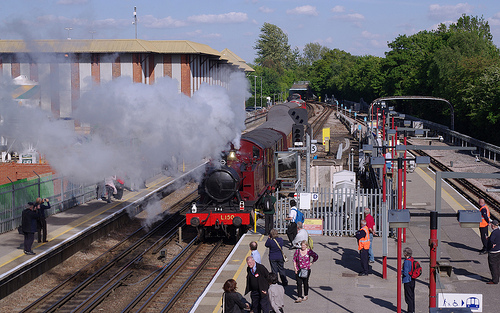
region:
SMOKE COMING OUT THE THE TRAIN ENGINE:
[16, 65, 371, 212]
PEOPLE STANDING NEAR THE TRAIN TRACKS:
[217, 172, 343, 312]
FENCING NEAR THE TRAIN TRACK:
[270, 162, 422, 267]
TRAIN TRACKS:
[60, 213, 232, 310]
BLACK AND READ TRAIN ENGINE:
[161, 103, 279, 252]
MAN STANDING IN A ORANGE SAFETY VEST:
[345, 210, 382, 272]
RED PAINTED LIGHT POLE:
[344, 87, 457, 302]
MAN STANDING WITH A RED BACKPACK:
[388, 232, 463, 312]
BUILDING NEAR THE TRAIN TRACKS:
[30, 14, 307, 211]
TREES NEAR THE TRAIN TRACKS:
[243, 15, 498, 132]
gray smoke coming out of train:
[0, 21, 249, 228]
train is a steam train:
[181, 93, 295, 243]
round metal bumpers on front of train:
[189, 217, 200, 228]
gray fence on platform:
[272, 186, 391, 239]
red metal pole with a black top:
[427, 209, 439, 311]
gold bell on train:
[225, 147, 239, 161]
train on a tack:
[110, 229, 249, 311]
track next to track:
[14, 185, 203, 311]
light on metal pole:
[386, 208, 433, 231]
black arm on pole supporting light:
[407, 210, 429, 219]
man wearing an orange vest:
[346, 204, 386, 279]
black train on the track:
[178, 142, 260, 234]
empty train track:
[377, 88, 498, 233]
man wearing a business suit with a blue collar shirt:
[236, 249, 276, 300]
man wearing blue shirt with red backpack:
[389, 239, 424, 303]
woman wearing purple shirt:
[288, 233, 323, 285]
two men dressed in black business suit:
[17, 184, 65, 260]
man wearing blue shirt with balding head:
[238, 227, 264, 265]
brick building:
[16, 14, 247, 140]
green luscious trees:
[289, 28, 485, 144]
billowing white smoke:
[60, 59, 246, 216]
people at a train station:
[221, 212, 322, 312]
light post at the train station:
[377, 206, 480, 311]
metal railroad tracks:
[43, 238, 209, 294]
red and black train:
[179, 90, 306, 244]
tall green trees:
[310, 25, 497, 100]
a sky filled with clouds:
[67, 6, 256, 38]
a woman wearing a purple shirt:
[292, 237, 322, 275]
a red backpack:
[400, 254, 427, 279]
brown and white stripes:
[45, 62, 139, 114]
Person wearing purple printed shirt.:
[300, 249, 318, 284]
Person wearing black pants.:
[301, 281, 313, 305]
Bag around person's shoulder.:
[291, 242, 317, 297]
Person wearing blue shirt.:
[265, 241, 285, 269]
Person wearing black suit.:
[243, 266, 275, 307]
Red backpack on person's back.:
[398, 254, 433, 288]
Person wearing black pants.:
[391, 282, 411, 304]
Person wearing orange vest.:
[458, 201, 492, 250]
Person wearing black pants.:
[471, 227, 496, 268]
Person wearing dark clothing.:
[13, 210, 42, 257]